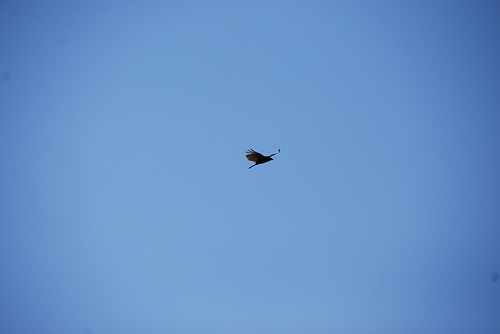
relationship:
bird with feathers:
[243, 146, 279, 168] [249, 154, 267, 161]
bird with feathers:
[227, 146, 302, 181] [233, 133, 263, 168]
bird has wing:
[243, 146, 279, 168] [246, 148, 267, 161]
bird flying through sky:
[243, 146, 279, 168] [6, 5, 498, 326]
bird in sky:
[243, 146, 279, 168] [6, 5, 498, 326]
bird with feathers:
[243, 146, 279, 168] [233, 147, 285, 165]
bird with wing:
[243, 146, 279, 168] [244, 148, 265, 163]